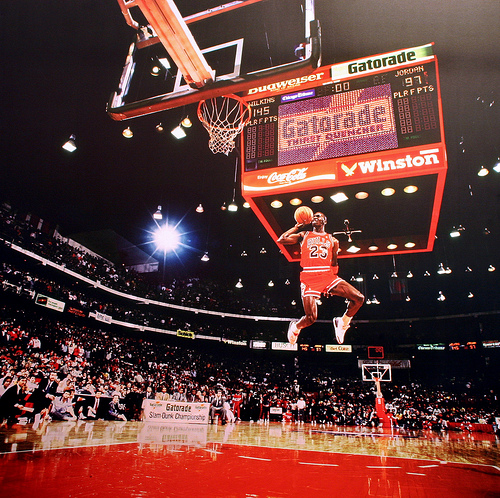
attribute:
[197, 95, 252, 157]
net — present, basketball 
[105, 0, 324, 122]
backboard — clear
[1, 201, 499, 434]
crowd — watching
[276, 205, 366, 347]
player — jumping, present, in air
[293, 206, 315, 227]
basketball — in hand, orange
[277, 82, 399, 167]
advertisement — electric, present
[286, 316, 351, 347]
shoes — white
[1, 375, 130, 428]
people — sitting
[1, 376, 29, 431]
man — coach, present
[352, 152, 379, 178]
letter — w